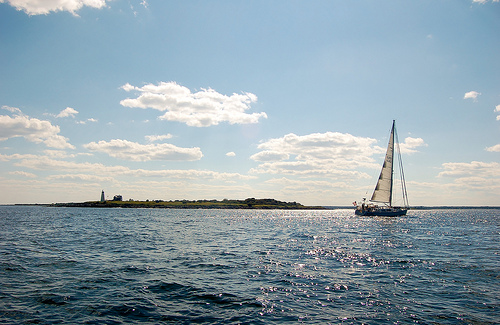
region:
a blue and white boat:
[347, 109, 411, 218]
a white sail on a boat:
[366, 117, 394, 204]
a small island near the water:
[2, 180, 496, 207]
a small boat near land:
[352, 110, 412, 217]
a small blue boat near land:
[345, 118, 420, 216]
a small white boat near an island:
[347, 116, 417, 218]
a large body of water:
[2, 204, 497, 324]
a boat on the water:
[346, 116, 414, 217]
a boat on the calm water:
[352, 114, 412, 219]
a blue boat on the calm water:
[348, 117, 416, 218]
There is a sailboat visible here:
[371, 129, 396, 223]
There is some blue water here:
[206, 233, 244, 293]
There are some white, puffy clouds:
[162, 86, 242, 199]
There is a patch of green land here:
[129, 189, 154, 230]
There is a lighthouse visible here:
[101, 185, 118, 241]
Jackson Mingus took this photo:
[91, 83, 164, 277]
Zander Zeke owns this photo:
[108, 88, 226, 290]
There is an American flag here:
[338, 190, 355, 211]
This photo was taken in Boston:
[85, 40, 177, 286]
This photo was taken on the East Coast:
[92, 42, 203, 312]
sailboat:
[360, 116, 412, 233]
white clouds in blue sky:
[77, 19, 124, 44]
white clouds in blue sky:
[157, 113, 228, 148]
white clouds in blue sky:
[228, 56, 326, 118]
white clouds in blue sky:
[60, 98, 112, 133]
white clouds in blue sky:
[260, 123, 320, 158]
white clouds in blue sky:
[427, 55, 467, 80]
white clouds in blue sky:
[430, 152, 487, 183]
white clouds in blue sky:
[197, 86, 247, 111]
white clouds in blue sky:
[101, 122, 168, 140]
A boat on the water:
[355, 117, 408, 217]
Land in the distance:
[18, 190, 331, 212]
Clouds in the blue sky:
[2, 1, 492, 201]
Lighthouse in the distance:
[99, 188, 106, 201]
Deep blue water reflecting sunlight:
[6, 206, 490, 323]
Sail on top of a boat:
[368, 118, 395, 204]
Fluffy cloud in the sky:
[116, 75, 268, 127]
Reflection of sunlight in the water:
[254, 206, 390, 319]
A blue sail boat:
[353, 198, 406, 214]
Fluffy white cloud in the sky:
[84, 138, 206, 161]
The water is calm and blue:
[66, 224, 379, 324]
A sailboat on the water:
[345, 118, 431, 227]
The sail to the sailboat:
[368, 109, 408, 204]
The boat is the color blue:
[353, 203, 410, 218]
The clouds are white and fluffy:
[143, 85, 253, 129]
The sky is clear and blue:
[163, 17, 446, 97]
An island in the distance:
[13, 173, 330, 211]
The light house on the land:
[97, 185, 112, 205]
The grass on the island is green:
[110, 189, 303, 214]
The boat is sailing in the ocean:
[341, 106, 423, 237]